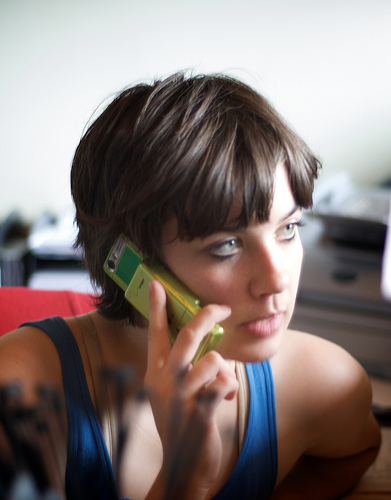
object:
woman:
[0, 67, 382, 500]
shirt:
[17, 315, 289, 500]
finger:
[200, 373, 239, 416]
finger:
[166, 304, 232, 376]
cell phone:
[103, 232, 225, 367]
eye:
[205, 238, 241, 255]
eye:
[277, 223, 295, 239]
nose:
[247, 239, 290, 299]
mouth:
[235, 309, 286, 339]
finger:
[179, 349, 237, 398]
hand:
[144, 278, 240, 481]